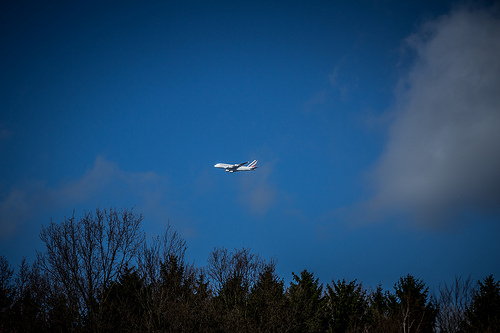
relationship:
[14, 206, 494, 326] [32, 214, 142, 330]
trees has sticks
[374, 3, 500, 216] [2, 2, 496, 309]
cloud are in sky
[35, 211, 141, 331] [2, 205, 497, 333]
tree in forest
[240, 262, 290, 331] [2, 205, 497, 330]
tree in forest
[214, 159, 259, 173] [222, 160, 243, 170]
airplane has wing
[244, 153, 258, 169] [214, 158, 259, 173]
tail on plane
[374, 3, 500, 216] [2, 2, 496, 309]
cloud in sky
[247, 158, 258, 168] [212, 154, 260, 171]
logo on plane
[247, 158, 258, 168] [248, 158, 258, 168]
logo on tail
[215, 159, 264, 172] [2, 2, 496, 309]
airplane in sky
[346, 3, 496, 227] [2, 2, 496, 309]
cloud in sky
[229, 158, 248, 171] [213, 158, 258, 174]
wing on airplane